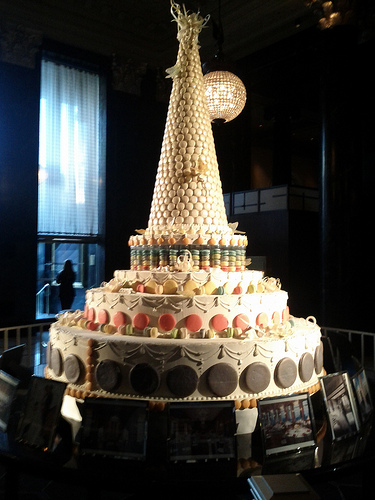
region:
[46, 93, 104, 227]
the curtain is sheer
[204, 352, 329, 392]
the cookies are black and round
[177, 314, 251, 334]
the candies are orange and round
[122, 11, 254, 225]
the cake has a pointed top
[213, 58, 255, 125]
the bulb is hanging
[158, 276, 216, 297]
the candies are yellow and round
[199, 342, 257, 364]
the cake is tan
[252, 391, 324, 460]
the picture is on the table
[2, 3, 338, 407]
the cake is pointed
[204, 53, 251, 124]
the globe is round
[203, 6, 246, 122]
round chandelier hanging from ceiling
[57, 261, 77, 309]
silhouette of person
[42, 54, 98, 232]
long white curtain over window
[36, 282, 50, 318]
part of railing next to person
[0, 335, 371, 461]
pictures surrounding cake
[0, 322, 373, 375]
white fencing around cake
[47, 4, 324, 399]
large cake on display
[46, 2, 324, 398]
large cake with five layers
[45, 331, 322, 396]
last level of cake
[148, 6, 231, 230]
long first layer of cake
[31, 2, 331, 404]
large decorative cake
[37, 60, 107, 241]
window in room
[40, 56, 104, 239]
window with curtain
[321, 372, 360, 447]
picture next to cake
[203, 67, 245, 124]
round chandelier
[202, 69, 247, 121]
white chandelier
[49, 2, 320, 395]
cake on table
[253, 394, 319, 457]
picture on table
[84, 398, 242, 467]
two pictures on table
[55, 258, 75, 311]
woman in black standing outside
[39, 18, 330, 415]
a very large cakae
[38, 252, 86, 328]
a woman in the doorway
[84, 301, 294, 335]
several pink round circles on cake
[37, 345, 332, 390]
several brown round circles on cake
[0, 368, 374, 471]
several pictures around bottom of cake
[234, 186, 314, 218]
US in white letters on wall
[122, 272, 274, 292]
smaller round yellow circles on cake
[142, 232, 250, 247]
even smaller round orange circles on cake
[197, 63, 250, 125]
a chandelier that looks like a disco ball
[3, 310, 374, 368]
a metal gate around cake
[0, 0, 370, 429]
the cake has 4 layers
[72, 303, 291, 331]
red circular decorations on cake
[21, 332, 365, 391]
brown circular decorations on cake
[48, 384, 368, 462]
pictures around the cake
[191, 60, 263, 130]
disco ball behind the cake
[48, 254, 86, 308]
woman standing in the background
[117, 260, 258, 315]
yellow decorations on the cake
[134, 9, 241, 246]
tower decoration on top layer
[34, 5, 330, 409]
the cake is white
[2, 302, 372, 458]
fence surrounding the cake